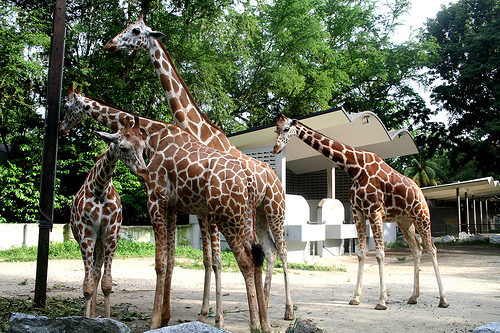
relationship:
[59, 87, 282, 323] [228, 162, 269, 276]
giraffe has tail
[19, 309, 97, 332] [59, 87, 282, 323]
rocks in front of giraffe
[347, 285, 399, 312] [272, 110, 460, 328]
hooves of giraffe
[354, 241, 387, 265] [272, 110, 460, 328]
knees of giraffe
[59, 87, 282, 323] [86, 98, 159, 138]
giraffe long neck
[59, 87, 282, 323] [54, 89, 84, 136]
giraffe fuzzy face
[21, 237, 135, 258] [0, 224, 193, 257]
grass growing in fence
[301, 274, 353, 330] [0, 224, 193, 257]
dirt on ground of fence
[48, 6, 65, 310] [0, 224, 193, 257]
pole in fence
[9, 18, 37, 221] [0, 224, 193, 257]
trees in fence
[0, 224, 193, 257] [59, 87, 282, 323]
fence behind giraffe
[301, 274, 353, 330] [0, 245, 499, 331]
dirt on bottom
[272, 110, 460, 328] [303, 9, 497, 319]
giraffe on right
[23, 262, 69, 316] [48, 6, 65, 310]
bottom of pole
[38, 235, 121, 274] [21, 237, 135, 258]
patch of grass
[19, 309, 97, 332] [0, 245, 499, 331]
rocks on bottom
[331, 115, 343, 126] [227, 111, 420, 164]
part of roof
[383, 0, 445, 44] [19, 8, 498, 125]
sky in background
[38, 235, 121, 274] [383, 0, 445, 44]
patch of sky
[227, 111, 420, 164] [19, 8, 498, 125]
roof in background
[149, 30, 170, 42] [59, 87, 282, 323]
ear of giraffe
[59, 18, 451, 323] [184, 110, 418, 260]
giraffes in zoo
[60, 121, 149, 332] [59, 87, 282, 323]
giraffe next to giraffe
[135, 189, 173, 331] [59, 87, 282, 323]
legs of giraffe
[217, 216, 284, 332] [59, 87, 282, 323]
legs of giraffe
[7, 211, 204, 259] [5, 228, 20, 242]
fence of wood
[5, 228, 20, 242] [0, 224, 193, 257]
wood in fence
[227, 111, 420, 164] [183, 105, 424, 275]
roof of shelter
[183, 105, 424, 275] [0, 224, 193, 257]
shelter on side of fence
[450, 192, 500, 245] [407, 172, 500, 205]
poles supporting roof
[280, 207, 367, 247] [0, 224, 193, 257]
feeders on fence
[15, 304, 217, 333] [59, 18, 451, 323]
stones in front of giraffes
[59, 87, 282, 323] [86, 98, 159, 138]
giraffe with neck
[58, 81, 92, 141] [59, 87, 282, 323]
head of giraffe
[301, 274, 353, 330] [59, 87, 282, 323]
dirt below giraffe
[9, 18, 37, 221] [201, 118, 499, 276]
trees behind building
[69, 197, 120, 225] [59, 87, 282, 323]
patch on giraffe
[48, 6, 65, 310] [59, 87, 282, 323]
pole next to giraffe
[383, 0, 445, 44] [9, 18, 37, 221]
sky above trees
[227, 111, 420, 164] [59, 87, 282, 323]
roof next to giraffe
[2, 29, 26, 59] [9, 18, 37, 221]
leaves on tree